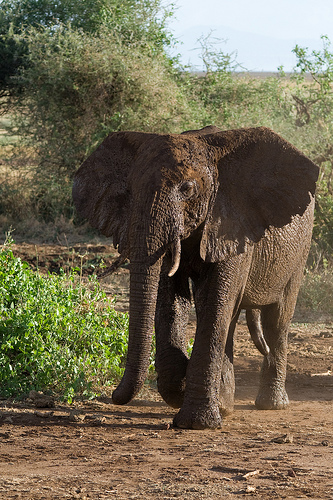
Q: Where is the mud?
A: Elephant.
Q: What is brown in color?
A: Ground.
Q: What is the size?
A: Huge.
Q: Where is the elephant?
A: Africa.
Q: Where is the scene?
A: In the jungle.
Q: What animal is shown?
A: Elephant.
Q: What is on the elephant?
A: Dirt.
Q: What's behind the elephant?
A: Vegetation.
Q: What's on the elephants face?
A: Husks.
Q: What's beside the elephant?
A: Plants.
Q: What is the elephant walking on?
A: Dirt.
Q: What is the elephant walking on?
A: A trail.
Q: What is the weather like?
A: Sunny.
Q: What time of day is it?
A: Afternoon.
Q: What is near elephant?
A: Bush.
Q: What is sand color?
A: Brown.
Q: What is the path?
A: Dry.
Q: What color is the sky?
A: Blue.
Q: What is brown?
A: Dirt.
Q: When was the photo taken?
A: Daytime.